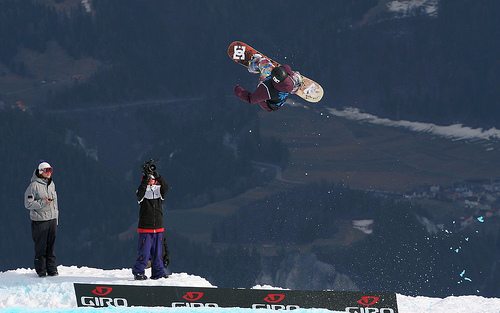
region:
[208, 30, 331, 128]
Man is on a snowboard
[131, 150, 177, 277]
Person is holding a camera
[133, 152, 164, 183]
The camera is black in color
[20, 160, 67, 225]
Person is wearing a gray coat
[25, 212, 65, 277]
Person is wearing dark colored pants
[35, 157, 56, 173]
Man is wearing goggles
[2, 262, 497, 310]
Snow is on the ground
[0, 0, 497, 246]
Tall trees in the background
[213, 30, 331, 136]
Snowboarder is in the air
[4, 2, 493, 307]
Photo was taken outdoors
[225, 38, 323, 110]
snowboarder flying through air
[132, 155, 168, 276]
man recording snowboarder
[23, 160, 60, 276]
person watching snow boarder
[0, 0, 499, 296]
land and trees in background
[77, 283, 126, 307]
GIRO logo and name on banner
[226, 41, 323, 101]
red, black and tan snowboard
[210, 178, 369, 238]
group of trees in the distance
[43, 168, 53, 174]
red goggles on person standing in snow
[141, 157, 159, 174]
black video camera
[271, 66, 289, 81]
black helmet on snowboarder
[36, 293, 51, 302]
Small patch of white snow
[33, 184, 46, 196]
Gray snow jacket of person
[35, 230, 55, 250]
Black pants of the person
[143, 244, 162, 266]
Blue pants of the person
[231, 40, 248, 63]
White and red part of the snowboard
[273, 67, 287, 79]
Black helmet of the snowboarder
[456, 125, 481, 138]
Snow on the hills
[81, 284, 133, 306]
Small section of the banner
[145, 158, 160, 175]
Black camera the pedestrian has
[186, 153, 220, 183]
Group of trees in the far distance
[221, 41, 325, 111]
A person snowboarding.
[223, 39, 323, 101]
A red and tan snow board.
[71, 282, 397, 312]
A black red and white sign.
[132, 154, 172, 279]
A person holding a camera.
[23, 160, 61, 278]
A person wearing snow goggles.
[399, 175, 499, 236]
A distant town.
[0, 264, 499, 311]
An area of snow.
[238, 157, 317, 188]
A gray winding road.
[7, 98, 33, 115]
Very distant buildings.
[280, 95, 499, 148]
A distant area of snow.